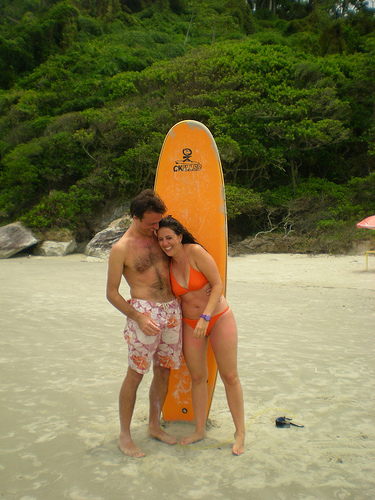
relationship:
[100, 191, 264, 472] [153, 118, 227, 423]
couple in front of surfboard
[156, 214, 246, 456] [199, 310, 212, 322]
lady has wrist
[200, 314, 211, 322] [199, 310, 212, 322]
purple watch on wrist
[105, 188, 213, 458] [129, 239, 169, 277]
man has hairy chest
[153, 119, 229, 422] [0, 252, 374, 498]
surfboard standing in sand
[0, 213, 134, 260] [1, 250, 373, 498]
large rocks lines beach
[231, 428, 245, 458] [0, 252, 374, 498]
foot in sand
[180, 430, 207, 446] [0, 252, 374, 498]
foot in sand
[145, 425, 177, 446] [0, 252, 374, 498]
foot in sand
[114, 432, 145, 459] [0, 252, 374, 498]
foot in sand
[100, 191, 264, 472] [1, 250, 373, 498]
couple on beach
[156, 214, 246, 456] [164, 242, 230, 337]
lady wearing bikini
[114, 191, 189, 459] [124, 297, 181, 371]
man wearing shorts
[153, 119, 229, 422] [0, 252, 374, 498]
surfboard standing on sand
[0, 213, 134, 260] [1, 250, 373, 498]
large rocks on side of beach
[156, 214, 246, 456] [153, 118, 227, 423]
lady standing in front of surfboard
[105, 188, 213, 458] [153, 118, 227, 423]
man standing in front of surfboard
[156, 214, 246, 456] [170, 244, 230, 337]
lady wearing bikini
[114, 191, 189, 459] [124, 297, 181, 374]
man wearing swim trunks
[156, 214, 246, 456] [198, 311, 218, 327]
lady wearing purple watch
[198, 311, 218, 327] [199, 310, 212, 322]
purple watch on wrist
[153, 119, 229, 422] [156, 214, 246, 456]
surfboard behind lady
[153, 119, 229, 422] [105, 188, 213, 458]
surfboard behind man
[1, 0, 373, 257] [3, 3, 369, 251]
foliage covering hill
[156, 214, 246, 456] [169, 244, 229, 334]
lady wearing swim clothes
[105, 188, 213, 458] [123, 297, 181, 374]
man wearing swim clothes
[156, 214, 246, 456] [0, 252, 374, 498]
lady standing on sand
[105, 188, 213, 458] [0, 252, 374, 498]
man standing on sand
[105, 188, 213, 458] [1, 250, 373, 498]
man at beach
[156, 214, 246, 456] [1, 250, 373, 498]
lady at beach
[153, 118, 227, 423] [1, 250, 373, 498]
surfboard at beach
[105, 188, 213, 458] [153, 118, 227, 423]
man with surfboard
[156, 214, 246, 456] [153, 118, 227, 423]
lady with surfboard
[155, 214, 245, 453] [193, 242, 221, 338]
lady has arm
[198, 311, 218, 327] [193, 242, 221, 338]
purple watch on arm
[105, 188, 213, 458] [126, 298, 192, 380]
man wearing man's trunks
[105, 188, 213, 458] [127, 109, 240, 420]
man with surfboard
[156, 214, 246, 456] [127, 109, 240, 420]
lady with surfboard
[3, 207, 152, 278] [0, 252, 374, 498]
large rocks at edge of sand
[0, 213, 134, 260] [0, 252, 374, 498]
large rocks at edge of sand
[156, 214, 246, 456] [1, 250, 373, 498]
lady standing at beach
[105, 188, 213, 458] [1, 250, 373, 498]
man standing at beach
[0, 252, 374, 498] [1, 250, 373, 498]
sand at beach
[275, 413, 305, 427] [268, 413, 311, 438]
strap on object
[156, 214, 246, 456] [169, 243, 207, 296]
lady wearing bikini top